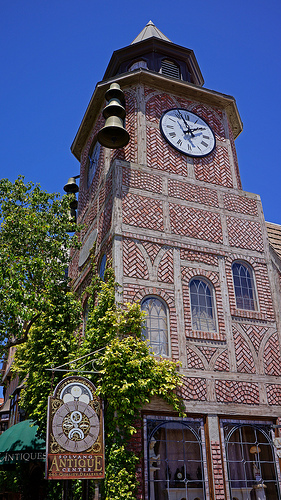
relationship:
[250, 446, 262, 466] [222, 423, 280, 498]
lamp in window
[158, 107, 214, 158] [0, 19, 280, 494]
clock on building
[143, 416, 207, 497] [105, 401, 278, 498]
glass windows on ground floor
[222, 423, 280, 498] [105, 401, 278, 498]
window on ground floor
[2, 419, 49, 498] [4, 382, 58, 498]
entryway to antique store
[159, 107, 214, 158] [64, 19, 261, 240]
clock on building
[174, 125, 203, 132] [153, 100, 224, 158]
hand on clock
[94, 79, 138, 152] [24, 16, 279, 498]
bells on building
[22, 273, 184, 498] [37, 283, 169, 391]
tree has leaves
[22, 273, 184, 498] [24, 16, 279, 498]
tree next to building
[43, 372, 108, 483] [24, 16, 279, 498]
sign in front of building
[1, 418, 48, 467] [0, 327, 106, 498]
awning in front of antique store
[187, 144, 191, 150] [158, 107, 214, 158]
six on clock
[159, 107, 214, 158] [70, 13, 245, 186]
clock on tower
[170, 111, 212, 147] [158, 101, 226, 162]
face on clock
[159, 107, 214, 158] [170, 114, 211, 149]
clock has roman numerals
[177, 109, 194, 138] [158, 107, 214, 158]
hand on clock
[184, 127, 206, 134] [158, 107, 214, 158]
hand on clock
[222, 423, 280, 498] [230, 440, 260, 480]
window has panes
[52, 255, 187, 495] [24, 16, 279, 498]
ivy climbing up building